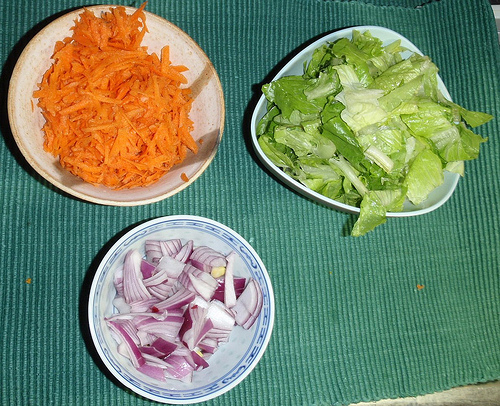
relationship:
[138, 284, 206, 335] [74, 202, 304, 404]
onions on plate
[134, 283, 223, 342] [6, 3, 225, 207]
object on bowl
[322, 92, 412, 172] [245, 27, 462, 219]
object on plate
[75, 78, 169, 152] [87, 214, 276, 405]
object on bowl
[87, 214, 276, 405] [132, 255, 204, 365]
bowl of onions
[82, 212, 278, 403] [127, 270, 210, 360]
bowl of onions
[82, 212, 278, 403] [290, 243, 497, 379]
bowl on placemat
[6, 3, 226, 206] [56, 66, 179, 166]
bowl of carrots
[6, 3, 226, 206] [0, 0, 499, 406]
bowl on cloth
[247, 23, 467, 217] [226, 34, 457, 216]
bowl of lettuce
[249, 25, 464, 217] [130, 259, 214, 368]
bowl of onions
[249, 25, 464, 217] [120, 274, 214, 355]
bowl with onions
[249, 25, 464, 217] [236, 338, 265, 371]
bowl with trim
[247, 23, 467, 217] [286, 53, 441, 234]
bowl with lettuce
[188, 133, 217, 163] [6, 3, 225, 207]
shadow on bowl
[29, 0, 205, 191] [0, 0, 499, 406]
ingredients on cloth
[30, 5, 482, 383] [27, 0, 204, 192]
trio of ingredients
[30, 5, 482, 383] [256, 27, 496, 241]
trio of ingredients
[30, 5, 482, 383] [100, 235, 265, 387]
trio of ingredients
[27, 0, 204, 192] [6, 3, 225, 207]
ingredients on bowl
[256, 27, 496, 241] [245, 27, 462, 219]
ingredients on plate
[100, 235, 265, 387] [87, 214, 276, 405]
ingredients on bowl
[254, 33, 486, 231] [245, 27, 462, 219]
lettuce on plate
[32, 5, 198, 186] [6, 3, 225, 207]
carrots on bowl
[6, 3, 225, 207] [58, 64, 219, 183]
bowl with pattern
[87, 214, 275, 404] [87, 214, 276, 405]
rim of bowl